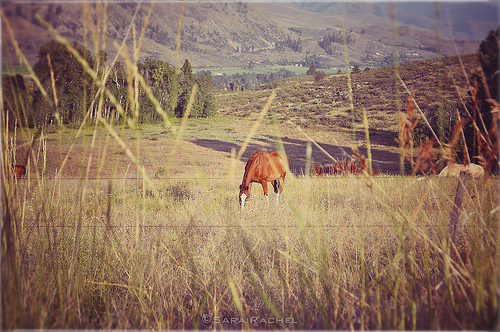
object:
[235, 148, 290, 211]
horse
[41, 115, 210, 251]
field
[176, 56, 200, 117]
trees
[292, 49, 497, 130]
hill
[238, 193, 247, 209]
stripe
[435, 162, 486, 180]
rock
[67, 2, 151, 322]
weeds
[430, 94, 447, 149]
tree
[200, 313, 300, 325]
words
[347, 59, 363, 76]
trees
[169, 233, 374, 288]
grass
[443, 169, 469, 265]
post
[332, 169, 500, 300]
fence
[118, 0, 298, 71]
mountains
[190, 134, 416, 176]
shadows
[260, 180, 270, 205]
legs